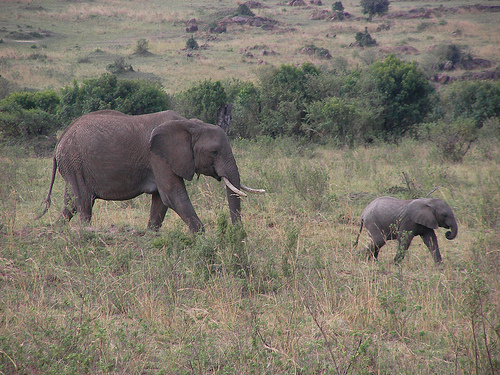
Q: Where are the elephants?
A: In a field.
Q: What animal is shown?
A: Elephant.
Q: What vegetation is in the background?
A: Trees.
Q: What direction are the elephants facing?
A: Right.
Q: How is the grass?
A: Brown.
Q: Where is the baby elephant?
A: Front.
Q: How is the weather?
A: Clear.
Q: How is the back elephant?
A: Grown.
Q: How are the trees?
A: Green.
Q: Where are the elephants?
A: Field.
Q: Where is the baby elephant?
A: In front.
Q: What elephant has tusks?
A: Adult on left.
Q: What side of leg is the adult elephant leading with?
A: Right.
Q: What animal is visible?
A: Elephant.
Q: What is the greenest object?
A: Trees.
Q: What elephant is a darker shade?
A: Adult.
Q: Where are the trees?
A: Behind the elephants.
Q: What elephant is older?
A: Left.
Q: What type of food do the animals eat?
A: Plants.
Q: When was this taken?
A: During the day.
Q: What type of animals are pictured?
A: Elephants.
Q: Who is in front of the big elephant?
A: A small elephant.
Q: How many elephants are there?
A: Two.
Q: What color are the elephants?
A: Grey.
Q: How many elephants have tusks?
A: One.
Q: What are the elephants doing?
A: Walking.